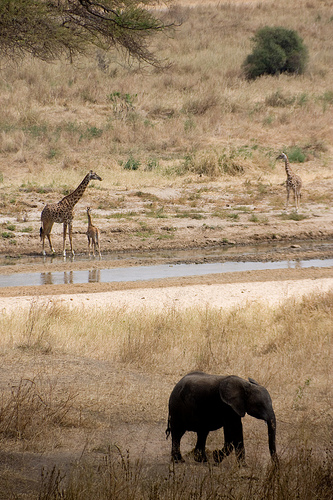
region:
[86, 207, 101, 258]
young giraffe by a large giraffe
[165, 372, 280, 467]
gray elephant walking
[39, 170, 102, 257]
large giraffe standing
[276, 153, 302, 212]
giraffe standing alone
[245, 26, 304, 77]
green bush in the field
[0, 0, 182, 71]
branches of a green tree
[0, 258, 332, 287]
small river going through the field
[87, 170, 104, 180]
head of a giraffe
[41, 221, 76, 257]
legs of a giraffe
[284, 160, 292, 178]
neck of a giraffe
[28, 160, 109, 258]
The giraffe is standing.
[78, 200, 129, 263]
The giraffe is standing.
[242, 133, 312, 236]
The giraffe is standing.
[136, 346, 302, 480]
The elephant is standing.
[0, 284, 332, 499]
The vegetation is brown.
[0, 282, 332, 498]
The vegetation is overgrown.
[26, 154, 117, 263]
The small giraffe is next to a larger one.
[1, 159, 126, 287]
The giraffe's are standing in a puddle.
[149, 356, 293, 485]
The elephant's trunk is hanging down.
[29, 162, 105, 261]
The giraffe is brown and tan.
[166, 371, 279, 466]
An elephant in the grass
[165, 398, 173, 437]
The tail of the elephant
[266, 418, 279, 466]
The trunk of the elephant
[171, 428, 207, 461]
The back legs of the elephant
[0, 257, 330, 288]
Water near the giraffes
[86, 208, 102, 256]
A small giraffe by the water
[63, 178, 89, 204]
The giraffe has a long neck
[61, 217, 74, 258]
The front legs of the giraffe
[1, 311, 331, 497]
Grass beneath the elephant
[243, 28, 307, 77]
A green bush behind the giraffes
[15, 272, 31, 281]
Small ripples in the water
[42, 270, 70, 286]
Small ripples in the water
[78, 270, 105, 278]
Small ripples in the water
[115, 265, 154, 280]
Small ripples in the water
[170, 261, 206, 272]
Small ripples in the water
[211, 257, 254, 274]
Small ripples in the water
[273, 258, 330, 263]
Small ripples in the water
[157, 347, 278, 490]
Elephant standing in the field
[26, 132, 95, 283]
Giraffe standing in the field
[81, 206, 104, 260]
Giraffe standing in the field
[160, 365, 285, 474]
elephant in the field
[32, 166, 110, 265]
giraffe and baby in the field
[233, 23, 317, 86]
bush in the field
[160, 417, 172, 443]
tail on the elephant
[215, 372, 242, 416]
ear on the elephant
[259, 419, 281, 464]
trunk of the elephant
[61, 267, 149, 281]
water in the pond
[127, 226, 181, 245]
grass patches on the ground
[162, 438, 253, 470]
legs on the ground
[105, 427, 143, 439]
dirt on the ground